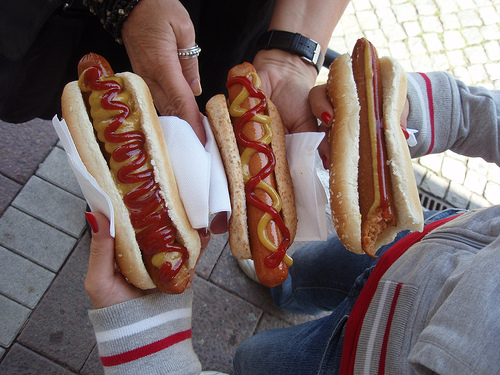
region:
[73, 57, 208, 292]
The hot dog on the left.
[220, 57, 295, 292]
The hot dog in the middle.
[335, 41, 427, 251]
The hot dog on the right.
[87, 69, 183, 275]
The ketchup on the hot dog on the left.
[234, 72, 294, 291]
The ketchup on the hot dog in the middle.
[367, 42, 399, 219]
The ketchup on the hot dog on the right.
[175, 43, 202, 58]
The ring on the person's finger.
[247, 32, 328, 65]
The black watch band on the person's wrist.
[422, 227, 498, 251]
The zipper on the gray sweater.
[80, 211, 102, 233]
The red thumb nail of the person holding the hot dogs.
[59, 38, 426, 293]
Three hot dogs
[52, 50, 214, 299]
A hot dog on a white napkin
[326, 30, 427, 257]
A hot dog with a bite taken out of it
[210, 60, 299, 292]
A hot dog with ketchup and mustard on it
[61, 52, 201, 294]
A hot dog in a bun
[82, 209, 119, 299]
A woman's thumb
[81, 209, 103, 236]
A thumb nail with red nail polish on it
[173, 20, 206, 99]
A woman with a silver ring on her thumb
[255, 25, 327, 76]
A black watch band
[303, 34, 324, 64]
A silver buckle on a black watch banc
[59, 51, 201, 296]
hot dog topped with ketchup and mustard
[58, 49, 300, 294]
two hot dogs topped with ketchup and mustard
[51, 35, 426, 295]
three hot dogs topped with mustard and ketchup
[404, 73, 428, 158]
white stripe on a sweaters cuff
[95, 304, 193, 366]
red and white stripes on a sweaters cuff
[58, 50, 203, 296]
hot dogs with a swirl of ketchup and mustard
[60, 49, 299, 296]
two hot dogs with a swirl of ketchup and mustard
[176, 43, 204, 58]
silver ring on a person's thumb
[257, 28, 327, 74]
black watch on a wrist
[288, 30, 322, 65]
buckle of a watch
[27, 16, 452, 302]
three hot dogs in the picture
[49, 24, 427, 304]
ketchup and mustard on the hot dogs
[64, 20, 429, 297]
there are different designs of ketchup and mustard on the hot dogs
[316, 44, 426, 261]
someone took a bite from this hot dog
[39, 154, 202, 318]
a woman's hand is holding this hot dog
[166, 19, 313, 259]
the person that is holding the hot dog has on a ring and a watch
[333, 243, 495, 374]
this jacket is gray with red and white trim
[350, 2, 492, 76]
the ground is made of brick pavers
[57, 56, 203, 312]
this hot dog is covered with ketchup and mustard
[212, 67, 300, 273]
this ketchup and mustard designed is swirly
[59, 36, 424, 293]
three hot dogs held by two diners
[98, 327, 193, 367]
red stripe on the sleeve of a gray jacket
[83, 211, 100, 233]
red nail polish on a thumb nail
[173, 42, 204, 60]
silver beaded ring on a thumb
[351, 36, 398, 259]
hot dog with a bite missing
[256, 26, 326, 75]
black watch with a silver buckle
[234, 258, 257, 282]
white sneaker on the ground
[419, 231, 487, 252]
zipper on a gray jacket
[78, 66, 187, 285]
ketchup and mustard heavily applied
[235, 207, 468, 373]
faded blue jeans